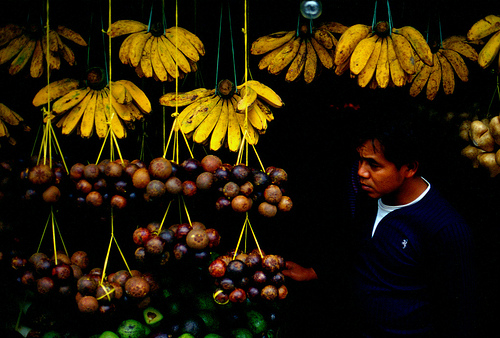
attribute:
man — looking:
[347, 132, 486, 337]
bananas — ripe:
[39, 77, 153, 140]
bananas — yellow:
[157, 79, 282, 153]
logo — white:
[400, 238, 410, 249]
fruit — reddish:
[207, 152, 276, 216]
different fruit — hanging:
[0, 5, 292, 337]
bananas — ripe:
[94, 13, 211, 87]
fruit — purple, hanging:
[22, 162, 289, 217]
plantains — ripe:
[3, 18, 498, 153]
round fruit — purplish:
[160, 135, 323, 221]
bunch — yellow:
[1, 102, 42, 139]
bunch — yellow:
[0, 25, 92, 76]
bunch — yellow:
[33, 72, 153, 139]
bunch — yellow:
[105, 16, 205, 86]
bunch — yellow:
[156, 77, 286, 149]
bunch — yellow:
[245, 17, 352, 77]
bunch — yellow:
[332, 20, 434, 88]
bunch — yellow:
[400, 33, 479, 99]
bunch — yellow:
[463, 9, 498, 70]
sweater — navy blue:
[348, 164, 480, 336]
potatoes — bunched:
[445, 112, 498, 182]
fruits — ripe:
[17, 235, 170, 324]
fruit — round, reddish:
[199, 229, 319, 307]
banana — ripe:
[250, 27, 296, 54]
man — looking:
[329, 122, 486, 329]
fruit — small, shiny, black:
[205, 248, 287, 303]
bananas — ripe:
[334, 18, 448, 81]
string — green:
[367, 3, 397, 38]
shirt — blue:
[349, 208, 494, 322]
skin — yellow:
[193, 103, 225, 130]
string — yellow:
[237, 14, 258, 166]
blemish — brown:
[184, 112, 205, 130]